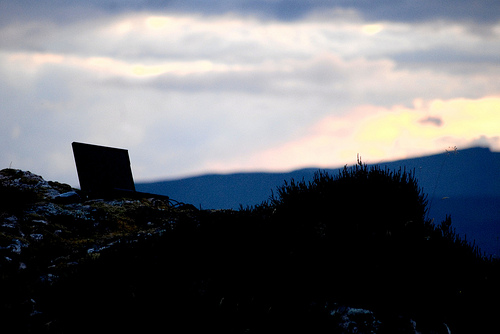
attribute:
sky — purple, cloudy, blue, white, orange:
[20, 14, 445, 125]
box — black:
[64, 141, 163, 198]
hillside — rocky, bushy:
[13, 175, 183, 333]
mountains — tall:
[175, 148, 498, 225]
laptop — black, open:
[68, 139, 152, 192]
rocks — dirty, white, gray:
[6, 182, 172, 279]